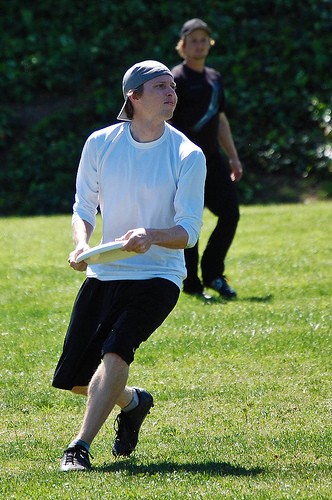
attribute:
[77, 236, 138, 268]
frisbee — white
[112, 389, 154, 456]
cleat — black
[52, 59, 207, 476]
man — throwing, playing, standing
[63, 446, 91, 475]
cleat — black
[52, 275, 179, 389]
shorts — black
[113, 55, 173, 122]
hat — backwards, grey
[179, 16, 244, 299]
man — standing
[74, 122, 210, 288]
shirt — long-sleeved, white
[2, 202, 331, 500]
grass — short, green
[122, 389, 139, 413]
sock — grey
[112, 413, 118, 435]
lace — black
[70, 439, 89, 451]
sock — short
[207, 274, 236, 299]
shoe — black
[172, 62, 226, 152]
shirt — black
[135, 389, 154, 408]
heel — lifted